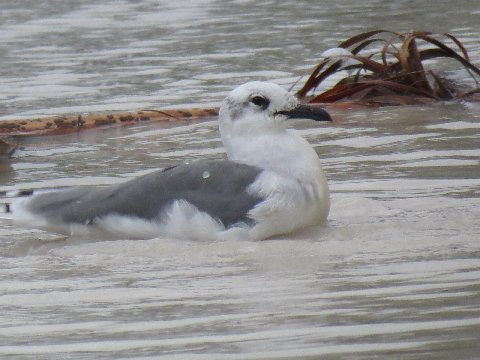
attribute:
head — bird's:
[215, 77, 334, 145]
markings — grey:
[224, 94, 252, 122]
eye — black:
[247, 91, 276, 111]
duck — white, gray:
[11, 87, 343, 242]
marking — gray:
[222, 96, 250, 128]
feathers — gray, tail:
[11, 164, 276, 249]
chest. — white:
[272, 123, 335, 230]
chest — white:
[274, 130, 331, 195]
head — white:
[216, 80, 332, 134]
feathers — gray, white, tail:
[2, 185, 77, 234]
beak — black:
[275, 106, 332, 122]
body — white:
[2, 161, 331, 240]